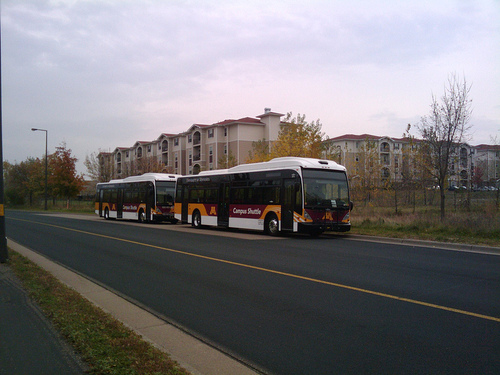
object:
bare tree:
[418, 73, 477, 224]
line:
[17, 203, 499, 373]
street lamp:
[31, 128, 49, 211]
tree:
[277, 109, 322, 162]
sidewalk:
[39, 211, 102, 221]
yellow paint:
[169, 248, 378, 294]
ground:
[383, 172, 408, 190]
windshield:
[302, 169, 349, 209]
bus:
[94, 172, 184, 223]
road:
[158, 230, 488, 332]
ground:
[4, 272, 97, 369]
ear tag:
[39, 295, 121, 360]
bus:
[173, 156, 354, 236]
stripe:
[262, 255, 496, 363]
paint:
[189, 204, 206, 212]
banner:
[209, 204, 300, 232]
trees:
[1, 145, 77, 207]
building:
[96, 107, 304, 186]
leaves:
[53, 166, 72, 187]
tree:
[406, 79, 478, 222]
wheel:
[264, 211, 279, 237]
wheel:
[192, 208, 202, 229]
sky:
[0, 0, 499, 119]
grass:
[30, 281, 141, 373]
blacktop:
[197, 240, 482, 361]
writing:
[233, 207, 262, 215]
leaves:
[258, 128, 328, 158]